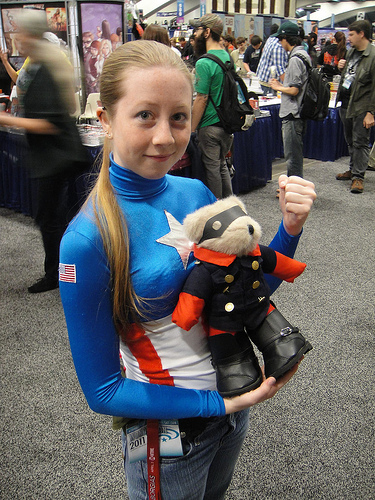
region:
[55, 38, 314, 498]
a young girl with blonde hair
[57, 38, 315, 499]
a young girl wearing a captain america shirt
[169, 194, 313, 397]
a teddy bear wearing a black mask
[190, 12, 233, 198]
a bearded man wearing a green shirt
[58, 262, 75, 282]
a United States flag patch attached to a shirt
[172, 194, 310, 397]
a teddy bear wearing black boots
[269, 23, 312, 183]
a man wearing a grey shirt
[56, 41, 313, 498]
a young girl making a fist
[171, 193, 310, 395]
a teddy bear wearing an orange shirt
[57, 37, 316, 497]
a young girl with a fair complextion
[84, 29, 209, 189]
The girl has light hair.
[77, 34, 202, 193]
The girls hair is straight.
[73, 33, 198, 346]
The girls hair is long.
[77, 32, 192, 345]
The girls hair is in a ponytail.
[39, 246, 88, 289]
The girls shirt has a flag on the sleeve.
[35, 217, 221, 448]
The girls shirt sleeve is long.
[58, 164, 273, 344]
The girls shirt is blue on top.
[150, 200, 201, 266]
The girls shirt has a star.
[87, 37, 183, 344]
girl has brown hair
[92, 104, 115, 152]
girl is wearing earring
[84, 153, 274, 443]
red white and blue shirt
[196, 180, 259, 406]
girl is holding bear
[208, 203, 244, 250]
bear has black mask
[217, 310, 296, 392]
bear has black boots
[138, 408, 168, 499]
girl has red lanyard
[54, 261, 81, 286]
A small American flag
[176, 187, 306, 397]
A stuffed bear in a costume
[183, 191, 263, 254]
Stuffed bear with a black mask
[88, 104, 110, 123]
A black and long spikey stud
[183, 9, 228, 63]
A man with a long beard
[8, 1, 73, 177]
Blurred image on the background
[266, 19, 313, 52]
A boy wearing a green cap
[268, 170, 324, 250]
A left fist hand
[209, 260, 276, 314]
There are six golden buttons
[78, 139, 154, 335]
Long blonde hair on a blue longsleeve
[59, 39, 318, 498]
girl holding teddy bear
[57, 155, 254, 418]
long sleeved blue shirt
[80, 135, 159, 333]
long thin blonde hair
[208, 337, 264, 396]
small round black boot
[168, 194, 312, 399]
stuffed bear dressed in clothes and mask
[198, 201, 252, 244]
gray mask covering stuffed bear's eyes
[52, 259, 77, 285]
emblem of United States flag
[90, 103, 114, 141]
two earrings in right ear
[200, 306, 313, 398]
black boots with buckles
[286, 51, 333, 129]
black backpack strapped on young man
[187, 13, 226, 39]
ball cap covering young man's head